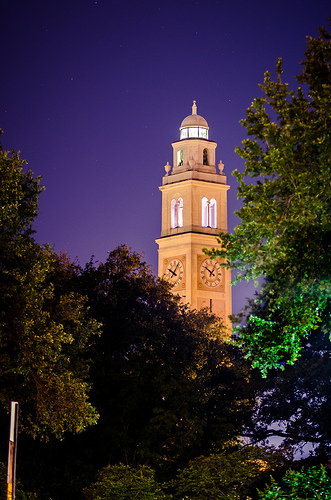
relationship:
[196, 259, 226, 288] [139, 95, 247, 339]
clock on tower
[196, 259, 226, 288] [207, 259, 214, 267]
clock has roman numerals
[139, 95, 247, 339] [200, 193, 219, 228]
tower has window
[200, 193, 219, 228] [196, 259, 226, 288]
window above clock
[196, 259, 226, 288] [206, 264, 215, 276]
clock has dial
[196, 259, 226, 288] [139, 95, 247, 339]
clock mounted on tower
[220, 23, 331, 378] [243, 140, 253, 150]
tree has leaf